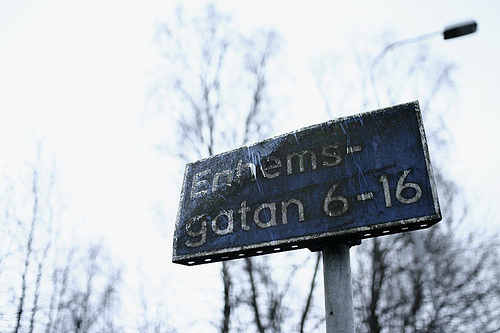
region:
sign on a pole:
[199, 120, 436, 242]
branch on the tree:
[428, 263, 459, 320]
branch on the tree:
[371, 272, 403, 317]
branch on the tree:
[72, 273, 117, 331]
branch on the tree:
[296, 280, 319, 330]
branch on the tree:
[236, 270, 252, 320]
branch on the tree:
[65, 258, 90, 323]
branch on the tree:
[451, 261, 486, 318]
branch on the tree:
[47, 249, 66, 329]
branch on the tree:
[257, 282, 278, 323]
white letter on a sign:
[390, 163, 427, 211]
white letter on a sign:
[375, 170, 396, 210]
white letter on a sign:
[319, 177, 356, 221]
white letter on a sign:
[275, 190, 312, 230]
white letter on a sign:
[252, 199, 281, 230]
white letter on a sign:
[232, 194, 254, 236]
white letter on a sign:
[209, 202, 239, 240]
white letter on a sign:
[182, 210, 212, 250]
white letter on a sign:
[317, 137, 342, 170]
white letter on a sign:
[280, 145, 322, 182]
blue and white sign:
[174, 96, 449, 277]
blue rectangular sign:
[169, 102, 425, 242]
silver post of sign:
[308, 243, 360, 331]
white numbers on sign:
[312, 163, 413, 225]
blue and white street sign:
[152, 98, 439, 265]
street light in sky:
[437, 15, 477, 42]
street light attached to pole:
[355, 17, 486, 76]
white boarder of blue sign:
[417, 100, 439, 232]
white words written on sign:
[184, 190, 308, 242]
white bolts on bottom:
[362, 223, 429, 246]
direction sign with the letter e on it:
[168, 90, 450, 276]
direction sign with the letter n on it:
[166, 85, 456, 287]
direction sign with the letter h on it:
[164, 97, 449, 270]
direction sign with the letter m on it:
[169, 92, 444, 284]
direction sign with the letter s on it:
[164, 95, 451, 270]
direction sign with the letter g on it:
[163, 94, 449, 271]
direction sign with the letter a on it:
[167, 87, 444, 284]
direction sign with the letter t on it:
[165, 95, 444, 282]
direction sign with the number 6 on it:
[168, 78, 449, 280]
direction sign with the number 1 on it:
[158, 89, 455, 278]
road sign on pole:
[171, 118, 438, 248]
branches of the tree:
[51, 245, 91, 316]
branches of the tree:
[377, 261, 421, 321]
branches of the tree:
[430, 257, 480, 325]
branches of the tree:
[436, 223, 463, 272]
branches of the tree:
[28, 212, 48, 326]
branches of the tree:
[248, 283, 286, 330]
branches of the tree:
[183, 108, 225, 160]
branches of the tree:
[455, 211, 480, 264]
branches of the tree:
[19, 178, 61, 256]